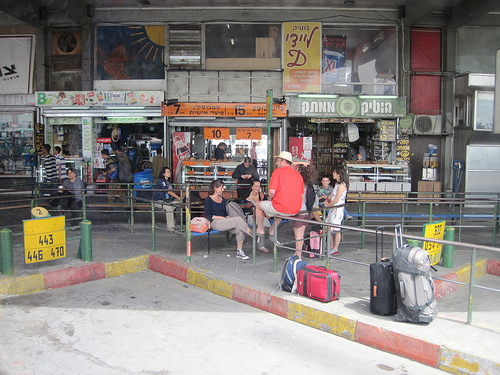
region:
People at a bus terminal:
[137, 137, 391, 243]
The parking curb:
[138, 230, 295, 332]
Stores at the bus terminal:
[86, 83, 461, 238]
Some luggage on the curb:
[270, 247, 483, 277]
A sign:
[16, 165, 133, 327]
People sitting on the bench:
[80, 126, 395, 266]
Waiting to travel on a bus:
[173, 180, 425, 257]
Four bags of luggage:
[249, 222, 473, 322]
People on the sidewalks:
[50, 99, 230, 226]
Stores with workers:
[180, 83, 377, 233]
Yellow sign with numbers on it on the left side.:
[20, 222, 65, 262]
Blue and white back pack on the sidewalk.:
[279, 250, 301, 292]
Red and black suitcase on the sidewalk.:
[302, 255, 341, 306]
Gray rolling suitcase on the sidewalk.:
[393, 230, 439, 325]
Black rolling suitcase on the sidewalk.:
[367, 233, 393, 317]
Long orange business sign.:
[163, 100, 285, 116]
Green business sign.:
[287, 95, 407, 118]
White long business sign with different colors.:
[33, 88, 162, 105]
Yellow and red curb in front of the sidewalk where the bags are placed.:
[150, 257, 462, 372]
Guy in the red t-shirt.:
[254, 151, 300, 215]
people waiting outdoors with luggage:
[165, 111, 475, 344]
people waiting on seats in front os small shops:
[158, 112, 333, 257]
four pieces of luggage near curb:
[276, 229, 436, 334]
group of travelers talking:
[172, 122, 343, 245]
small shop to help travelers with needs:
[271, 90, 409, 224]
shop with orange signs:
[162, 93, 267, 197]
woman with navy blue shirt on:
[186, 181, 237, 255]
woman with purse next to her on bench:
[168, 176, 249, 258]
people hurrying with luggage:
[90, 125, 146, 224]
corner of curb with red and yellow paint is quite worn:
[60, 247, 273, 332]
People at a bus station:
[57, 96, 330, 319]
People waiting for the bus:
[117, 138, 486, 335]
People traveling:
[45, 113, 351, 318]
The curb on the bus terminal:
[51, 192, 321, 365]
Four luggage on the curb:
[274, 243, 466, 309]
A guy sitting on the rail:
[239, 155, 336, 232]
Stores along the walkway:
[59, 65, 489, 240]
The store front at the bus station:
[150, 75, 306, 192]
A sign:
[17, 201, 77, 246]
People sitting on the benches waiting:
[46, 131, 303, 273]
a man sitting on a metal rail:
[251, 149, 304, 238]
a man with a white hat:
[273, 149, 299, 165]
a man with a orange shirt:
[266, 164, 306, 215]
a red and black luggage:
[294, 261, 341, 303]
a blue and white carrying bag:
[280, 254, 307, 295]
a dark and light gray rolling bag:
[392, 224, 440, 325]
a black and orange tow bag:
[369, 257, 398, 319]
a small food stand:
[163, 103, 286, 193]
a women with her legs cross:
[204, 179, 261, 259]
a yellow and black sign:
[20, 214, 68, 265]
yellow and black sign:
[26, 218, 60, 260]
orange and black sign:
[203, 125, 234, 140]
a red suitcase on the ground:
[296, 265, 332, 300]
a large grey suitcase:
[395, 245, 438, 322]